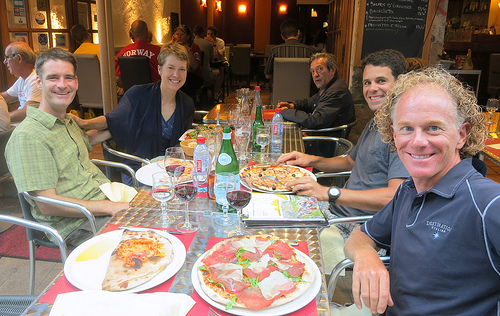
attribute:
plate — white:
[65, 226, 188, 292]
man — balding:
[330, 63, 500, 315]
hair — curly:
[371, 63, 491, 159]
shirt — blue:
[359, 157, 500, 314]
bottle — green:
[213, 125, 241, 214]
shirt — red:
[113, 40, 161, 86]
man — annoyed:
[277, 51, 358, 158]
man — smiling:
[5, 47, 139, 247]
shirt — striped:
[7, 103, 111, 245]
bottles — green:
[217, 103, 265, 213]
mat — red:
[188, 235, 317, 315]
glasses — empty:
[229, 85, 254, 159]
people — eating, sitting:
[20, 39, 491, 312]